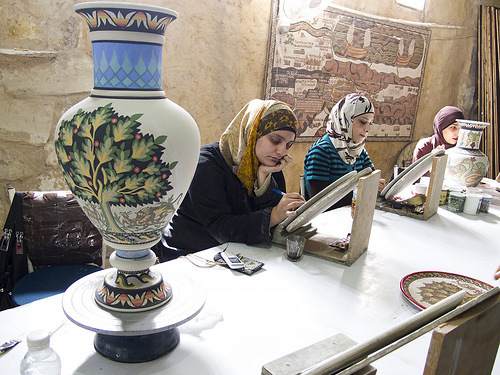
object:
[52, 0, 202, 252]
vase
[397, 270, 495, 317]
plate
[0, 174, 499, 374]
table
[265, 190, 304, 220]
hand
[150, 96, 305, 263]
woman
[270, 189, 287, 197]
art instrument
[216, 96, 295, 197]
hijab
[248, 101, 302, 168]
head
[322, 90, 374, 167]
hijab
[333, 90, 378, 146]
head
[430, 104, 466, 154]
hijab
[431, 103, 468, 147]
head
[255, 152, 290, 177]
hand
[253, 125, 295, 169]
face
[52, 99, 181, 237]
tree drawing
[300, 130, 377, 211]
shirt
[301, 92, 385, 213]
woman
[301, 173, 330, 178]
stripes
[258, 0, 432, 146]
art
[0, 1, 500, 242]
wall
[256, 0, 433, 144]
decoration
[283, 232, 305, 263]
glass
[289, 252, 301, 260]
liquid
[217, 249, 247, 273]
cellphone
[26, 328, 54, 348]
cap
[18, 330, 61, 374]
water bottle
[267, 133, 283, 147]
eye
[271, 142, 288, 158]
nose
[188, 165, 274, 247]
arm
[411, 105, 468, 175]
woman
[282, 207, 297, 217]
fingers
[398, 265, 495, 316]
trim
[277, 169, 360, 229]
plate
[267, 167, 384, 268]
wooden easel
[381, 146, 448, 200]
plate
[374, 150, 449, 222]
wooden easel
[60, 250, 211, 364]
display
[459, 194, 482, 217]
cups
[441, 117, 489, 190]
vase